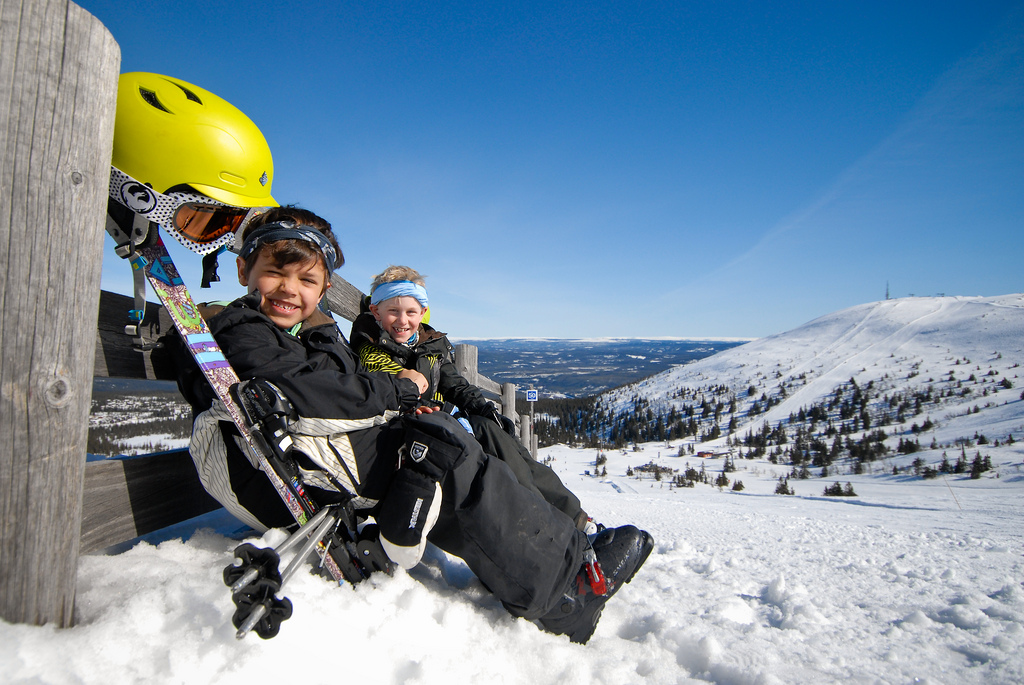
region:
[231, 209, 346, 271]
child wearing a black bandanna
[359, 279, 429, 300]
child wearing a blue bandanna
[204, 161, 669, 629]
two boys leaning against the fence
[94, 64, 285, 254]
yellow helmet on the fence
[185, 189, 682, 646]
two boys sitting in the snow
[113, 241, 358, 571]
ski pole leaning on the fence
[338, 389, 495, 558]
black gloves on the boy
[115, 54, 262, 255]
a yellow helmet on a fence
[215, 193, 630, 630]
two young boys sitting in the snow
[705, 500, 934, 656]
the snow covered with snow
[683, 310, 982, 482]
a hillside covered with snow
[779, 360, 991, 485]
a hillside covered with trees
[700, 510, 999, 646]
tracks in the snow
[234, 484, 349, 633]
two metal snow ski poles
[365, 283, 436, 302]
a boy wearing a blue head band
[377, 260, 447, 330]
a boy with blonde hair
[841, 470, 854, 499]
evergreen tree a the bottom of the hill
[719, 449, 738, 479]
evergreen tree a the bottom of the hill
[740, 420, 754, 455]
evergreen tree a the bottom of the hill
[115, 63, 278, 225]
plastic yellow snowboard helmet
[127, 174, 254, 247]
white patterned snow goggles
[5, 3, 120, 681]
wooden fence pole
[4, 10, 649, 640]
brown wooden fence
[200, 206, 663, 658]
child sitting next to helmet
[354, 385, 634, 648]
gray ski pants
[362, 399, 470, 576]
black and white mitten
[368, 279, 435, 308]
light blue headband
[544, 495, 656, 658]
gray ski boot with red clip